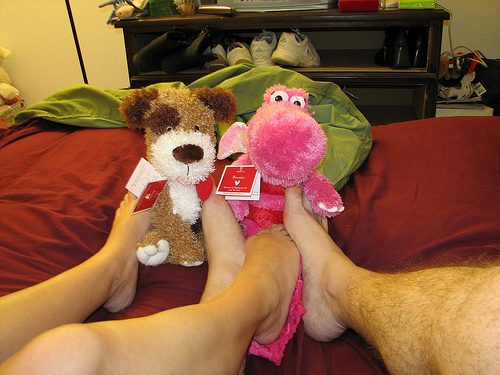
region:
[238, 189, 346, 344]
Bare feet on the bed.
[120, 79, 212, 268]
Stuffed dog on bed.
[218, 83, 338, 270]
Pink stuffed animal on bed.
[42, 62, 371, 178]
Green blanket behind animals.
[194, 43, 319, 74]
Tennis shoes on shelf.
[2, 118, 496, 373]
Red comforter on bed.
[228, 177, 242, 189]
White heart on tag.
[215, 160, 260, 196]
Red tag on stuffed animal.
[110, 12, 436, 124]
Wooden shelf in front of wall.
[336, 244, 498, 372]
Brown hair on leg.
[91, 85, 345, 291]
Two dolls are in bed.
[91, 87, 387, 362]
two person are holding dolls in legs.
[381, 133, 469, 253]
Bed sheet is red color.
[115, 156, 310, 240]
Dolls are tagged.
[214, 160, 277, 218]
tag is red and white color.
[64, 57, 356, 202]
Pant is green color.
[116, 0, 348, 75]
Shoe is in the rack.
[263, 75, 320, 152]
Eyes are black and white color.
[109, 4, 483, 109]
Rack is brown color.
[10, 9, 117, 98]
Wall is cream color.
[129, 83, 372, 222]
two stuffed animals on the bed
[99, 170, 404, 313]
two sets on feet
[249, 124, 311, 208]
stuffed animal is pink and red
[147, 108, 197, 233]
stuffed animal is a dog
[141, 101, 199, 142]
dog has a spot on his face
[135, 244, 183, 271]
dog's foot is white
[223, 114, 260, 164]
stuffed animal has wings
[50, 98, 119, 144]
bed cover is green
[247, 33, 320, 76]
shoes on the shelf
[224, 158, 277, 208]
red tag on the stuffed animals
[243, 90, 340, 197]
this is a doll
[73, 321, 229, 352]
this is a leg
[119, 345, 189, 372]
the leg is light skinned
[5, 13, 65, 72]
this is the wall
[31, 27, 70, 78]
the wall is cream in color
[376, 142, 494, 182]
this is a bed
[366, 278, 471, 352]
this is the hair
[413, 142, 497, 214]
the bed sheet is red in color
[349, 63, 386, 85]
this is a cupboard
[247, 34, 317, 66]
this is a pair of shoe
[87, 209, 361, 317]
feet on the stuffed animals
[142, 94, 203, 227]
dog stuffed animal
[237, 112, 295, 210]
hippo with wings stuffed animal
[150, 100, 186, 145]
dog has a brown spot on his eye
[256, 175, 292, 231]
hippo has red stripes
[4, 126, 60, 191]
bed sheets are maroon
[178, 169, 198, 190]
dog has his tongue out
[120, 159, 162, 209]
tag is open on the dog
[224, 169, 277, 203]
heart on the tag